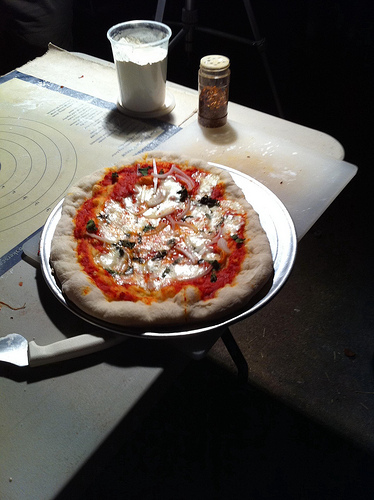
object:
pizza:
[50, 149, 272, 328]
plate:
[39, 159, 296, 338]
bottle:
[198, 55, 231, 128]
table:
[0, 52, 343, 498]